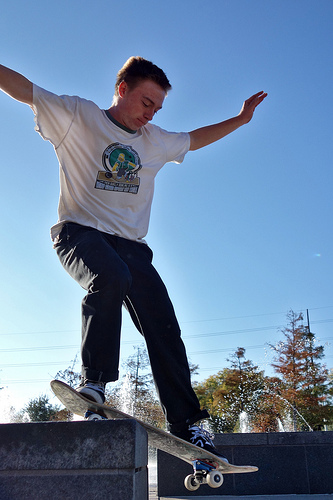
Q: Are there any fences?
A: No, there are no fences.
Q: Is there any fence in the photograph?
A: No, there are no fences.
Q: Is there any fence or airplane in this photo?
A: No, there are no fences or airplanes.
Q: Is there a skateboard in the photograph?
A: Yes, there is a skateboard.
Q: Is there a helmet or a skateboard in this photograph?
A: Yes, there is a skateboard.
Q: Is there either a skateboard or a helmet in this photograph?
A: Yes, there is a skateboard.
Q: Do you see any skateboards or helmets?
A: Yes, there is a skateboard.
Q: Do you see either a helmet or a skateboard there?
A: Yes, there is a skateboard.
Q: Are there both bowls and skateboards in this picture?
A: No, there is a skateboard but no bowls.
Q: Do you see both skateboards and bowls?
A: No, there is a skateboard but no bowls.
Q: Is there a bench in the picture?
A: No, there are no benches.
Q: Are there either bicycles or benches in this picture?
A: No, there are no benches or bicycles.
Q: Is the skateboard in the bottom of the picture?
A: Yes, the skateboard is in the bottom of the image.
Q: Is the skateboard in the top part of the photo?
A: No, the skateboard is in the bottom of the image.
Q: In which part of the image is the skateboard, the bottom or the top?
A: The skateboard is in the bottom of the image.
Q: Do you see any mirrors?
A: No, there are no mirrors.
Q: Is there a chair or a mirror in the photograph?
A: No, there are no mirrors or chairs.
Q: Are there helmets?
A: No, there are no helmets.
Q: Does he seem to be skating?
A: Yes, the boy is skating.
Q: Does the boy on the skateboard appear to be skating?
A: Yes, the boy is skating.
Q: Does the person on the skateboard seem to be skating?
A: Yes, the boy is skating.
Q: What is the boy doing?
A: The boy is skating.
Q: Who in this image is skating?
A: The boy is skating.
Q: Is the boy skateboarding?
A: No, the boy is skating.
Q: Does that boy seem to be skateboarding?
A: No, the boy is skating.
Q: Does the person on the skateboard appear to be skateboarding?
A: No, the boy is skating.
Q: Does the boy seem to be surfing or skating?
A: The boy is skating.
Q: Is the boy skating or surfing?
A: The boy is skating.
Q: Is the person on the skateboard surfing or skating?
A: The boy is skating.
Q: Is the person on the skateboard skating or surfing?
A: The boy is skating.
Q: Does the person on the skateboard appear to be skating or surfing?
A: The boy is skating.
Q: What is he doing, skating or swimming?
A: The boy is skating.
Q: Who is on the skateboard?
A: The boy is on the skateboard.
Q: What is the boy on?
A: The boy is on the skateboard.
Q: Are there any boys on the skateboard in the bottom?
A: Yes, there is a boy on the skateboard.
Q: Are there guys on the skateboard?
A: No, there is a boy on the skateboard.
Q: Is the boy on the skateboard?
A: Yes, the boy is on the skateboard.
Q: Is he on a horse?
A: No, the boy is on the skateboard.